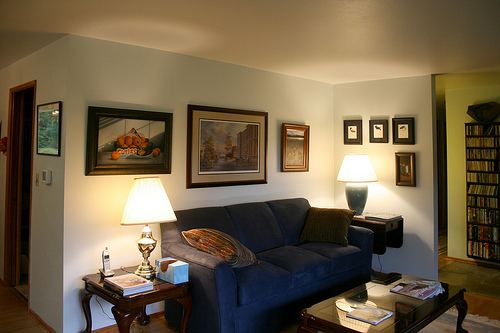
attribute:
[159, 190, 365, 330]
couch — blue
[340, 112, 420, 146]
pictures — black, white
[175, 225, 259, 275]
pillows — soft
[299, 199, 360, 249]
pillows — soft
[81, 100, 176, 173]
painting — framed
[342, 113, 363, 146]
cards — framed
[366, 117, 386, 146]
cards — framed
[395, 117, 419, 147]
cards — framed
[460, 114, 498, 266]
bookshelf — black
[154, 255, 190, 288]
box — tissue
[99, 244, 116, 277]
phone — landline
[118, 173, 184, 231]
lampshade — white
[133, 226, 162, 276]
base — silver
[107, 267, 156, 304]
book — hardcover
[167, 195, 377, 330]
couch — blue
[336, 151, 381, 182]
lampshade — white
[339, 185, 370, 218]
base — blue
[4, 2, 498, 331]
room — living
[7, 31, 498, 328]
room — living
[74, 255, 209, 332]
table — end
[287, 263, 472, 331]
table — coffee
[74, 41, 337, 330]
wall — white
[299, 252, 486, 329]
table — coffee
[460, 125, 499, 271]
shelf — full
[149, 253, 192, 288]
box — kleenex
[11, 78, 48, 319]
door way — open